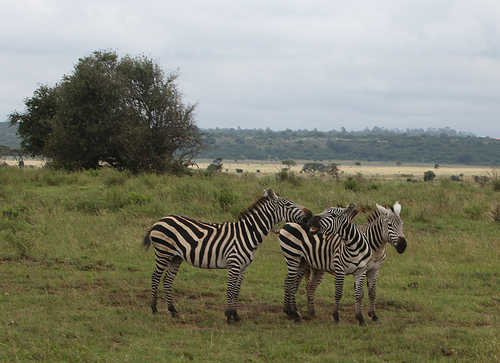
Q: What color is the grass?
A: Green.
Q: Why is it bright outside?
A: It's daytime.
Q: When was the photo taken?
A: Daytime.